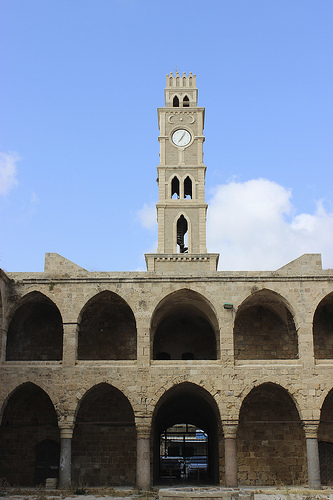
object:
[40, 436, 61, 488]
door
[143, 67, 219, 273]
building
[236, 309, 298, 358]
bricks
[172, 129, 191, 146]
clock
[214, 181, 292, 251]
white clouds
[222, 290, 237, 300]
bricks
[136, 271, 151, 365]
bricks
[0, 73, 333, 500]
building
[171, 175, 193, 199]
arches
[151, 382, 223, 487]
entrance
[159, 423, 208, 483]
gate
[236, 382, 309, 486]
entrace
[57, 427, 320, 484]
pillars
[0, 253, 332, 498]
building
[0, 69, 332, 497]
bricks